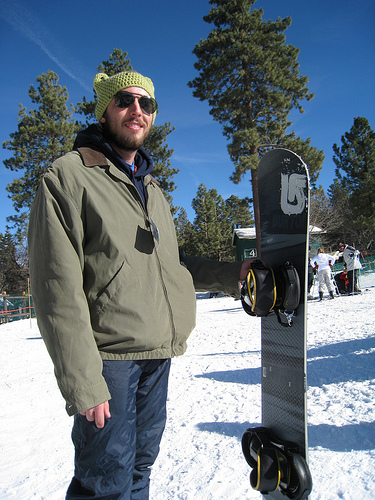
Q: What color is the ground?
A: White.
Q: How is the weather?
A: Cold.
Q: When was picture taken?
A: Daytime.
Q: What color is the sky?
A: Blue.